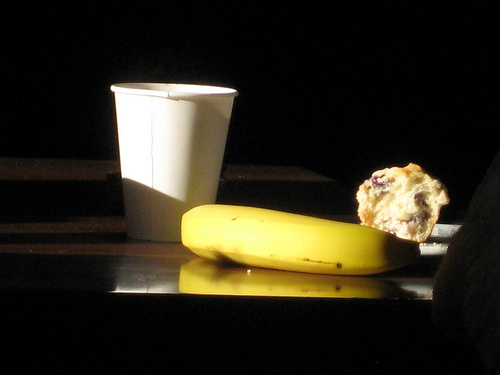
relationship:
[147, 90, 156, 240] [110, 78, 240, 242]
seam belonging to cup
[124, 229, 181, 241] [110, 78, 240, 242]
base belonging to cup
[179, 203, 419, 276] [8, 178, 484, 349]
banana on table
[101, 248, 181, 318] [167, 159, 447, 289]
table under food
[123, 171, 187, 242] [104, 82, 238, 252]
shadow on cup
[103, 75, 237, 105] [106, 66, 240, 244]
mouth of cup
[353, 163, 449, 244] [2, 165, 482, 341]
muffin on table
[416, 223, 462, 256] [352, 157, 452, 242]
plate under muffin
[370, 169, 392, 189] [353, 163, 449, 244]
fruit in muffin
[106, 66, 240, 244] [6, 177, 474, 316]
cup on table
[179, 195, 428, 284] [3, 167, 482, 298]
banana on table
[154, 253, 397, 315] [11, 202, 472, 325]
reflection on surface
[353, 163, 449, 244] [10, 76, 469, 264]
muffin in background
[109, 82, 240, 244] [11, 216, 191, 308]
cup casting shadow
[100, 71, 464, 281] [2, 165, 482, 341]
snack sitting on table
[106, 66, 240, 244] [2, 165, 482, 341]
cup sitting on table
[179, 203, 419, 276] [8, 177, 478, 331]
banana on table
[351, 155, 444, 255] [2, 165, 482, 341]
muffin on table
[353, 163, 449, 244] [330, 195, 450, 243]
muffin on plate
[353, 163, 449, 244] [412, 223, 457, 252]
muffin on plate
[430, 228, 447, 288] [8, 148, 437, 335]
plate on table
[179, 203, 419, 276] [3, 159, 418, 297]
banana on table